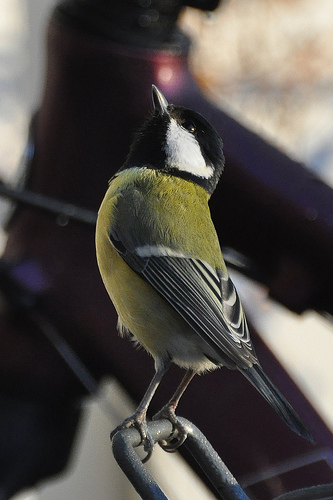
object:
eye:
[184, 123, 196, 132]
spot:
[163, 117, 213, 179]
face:
[143, 109, 217, 181]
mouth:
[149, 83, 169, 117]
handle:
[110, 414, 250, 500]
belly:
[93, 176, 147, 330]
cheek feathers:
[162, 116, 216, 183]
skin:
[163, 116, 215, 180]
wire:
[109, 412, 250, 500]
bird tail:
[235, 358, 320, 449]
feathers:
[94, 165, 318, 464]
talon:
[107, 409, 155, 465]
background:
[0, 0, 333, 500]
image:
[89, 82, 318, 465]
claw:
[150, 408, 188, 452]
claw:
[105, 415, 153, 467]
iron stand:
[109, 414, 253, 500]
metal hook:
[109, 415, 252, 500]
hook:
[108, 414, 153, 465]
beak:
[151, 84, 170, 115]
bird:
[94, 81, 319, 465]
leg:
[138, 360, 168, 408]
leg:
[163, 370, 192, 414]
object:
[0, 1, 331, 497]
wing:
[105, 185, 261, 371]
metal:
[221, 480, 244, 500]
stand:
[109, 415, 252, 500]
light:
[184, 420, 200, 433]